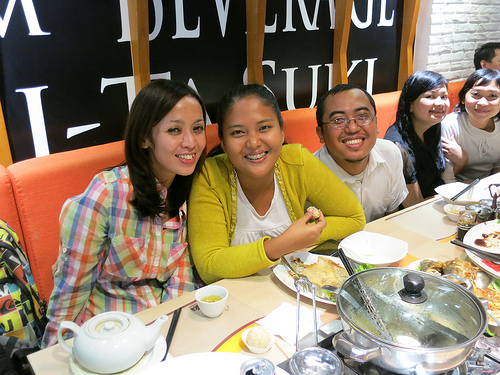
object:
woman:
[385, 69, 470, 211]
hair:
[395, 70, 449, 158]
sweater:
[186, 144, 366, 284]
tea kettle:
[57, 311, 170, 375]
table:
[26, 172, 500, 374]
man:
[314, 83, 409, 223]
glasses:
[320, 113, 376, 129]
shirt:
[311, 138, 409, 222]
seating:
[2, 81, 475, 305]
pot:
[333, 268, 487, 375]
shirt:
[42, 165, 205, 349]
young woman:
[187, 83, 367, 287]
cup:
[192, 284, 228, 319]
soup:
[201, 294, 223, 303]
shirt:
[382, 113, 447, 212]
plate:
[337, 230, 409, 267]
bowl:
[434, 181, 485, 205]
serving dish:
[464, 220, 498, 278]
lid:
[338, 268, 485, 351]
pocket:
[101, 236, 146, 277]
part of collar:
[363, 149, 388, 178]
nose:
[180, 129, 197, 150]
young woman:
[43, 79, 206, 349]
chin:
[169, 165, 196, 176]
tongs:
[449, 239, 499, 261]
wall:
[414, 1, 498, 87]